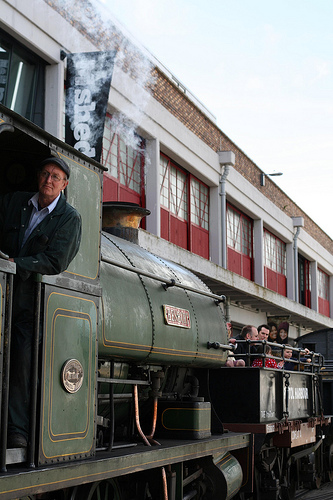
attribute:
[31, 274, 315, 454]
train — green, coal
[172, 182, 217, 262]
windows — red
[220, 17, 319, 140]
day — cloudy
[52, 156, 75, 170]
cap — flat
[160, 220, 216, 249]
panels — red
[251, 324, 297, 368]
people — standing, riding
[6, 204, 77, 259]
jacket — black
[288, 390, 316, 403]
text — white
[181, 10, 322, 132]
sky — cloudy, blue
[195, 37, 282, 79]
clouds — white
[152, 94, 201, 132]
bricks — brown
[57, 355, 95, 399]
attachment — gray, metal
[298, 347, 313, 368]
boy — small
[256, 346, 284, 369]
girl — small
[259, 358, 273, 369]
top — red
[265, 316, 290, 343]
banner — black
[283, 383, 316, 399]
wording — white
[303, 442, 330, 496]
wheel — large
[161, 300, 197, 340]
plate — gold, metallic, red